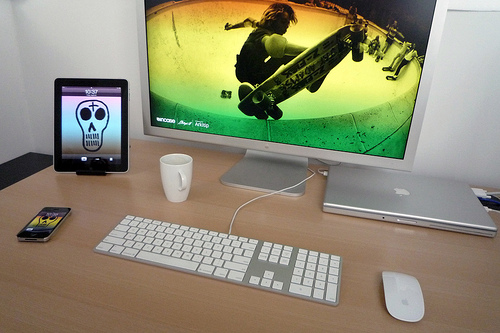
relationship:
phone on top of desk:
[17, 204, 70, 242] [2, 136, 498, 329]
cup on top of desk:
[160, 153, 193, 202] [2, 136, 498, 329]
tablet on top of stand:
[53, 78, 130, 169] [76, 166, 104, 175]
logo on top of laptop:
[392, 187, 410, 198] [323, 162, 498, 240]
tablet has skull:
[53, 78, 130, 169] [75, 98, 110, 151]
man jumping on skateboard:
[225, 4, 309, 121] [240, 20, 366, 119]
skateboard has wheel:
[240, 20, 366, 119] [350, 47, 365, 62]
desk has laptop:
[2, 136, 498, 329] [323, 162, 498, 240]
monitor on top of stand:
[138, 3, 447, 170] [221, 148, 311, 196]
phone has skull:
[17, 204, 70, 242] [37, 216, 57, 226]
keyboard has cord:
[96, 214, 343, 313] [229, 161, 315, 234]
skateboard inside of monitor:
[240, 20, 366, 119] [138, 3, 447, 170]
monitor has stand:
[138, 3, 447, 170] [221, 148, 311, 196]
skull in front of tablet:
[75, 98, 110, 151] [53, 78, 130, 169]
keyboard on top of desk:
[96, 214, 343, 313] [2, 136, 498, 329]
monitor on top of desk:
[138, 3, 447, 170] [2, 136, 498, 329]